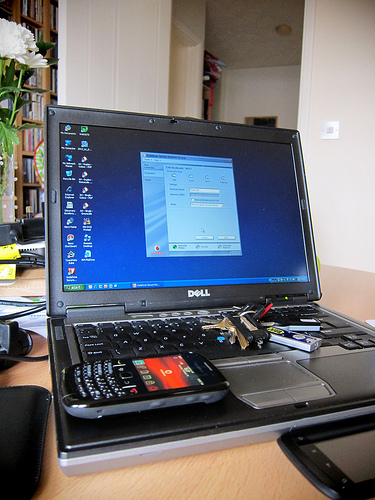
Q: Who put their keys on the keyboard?
A: The owner.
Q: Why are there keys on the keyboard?
A: For typing.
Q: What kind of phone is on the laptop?
A: Blackberry.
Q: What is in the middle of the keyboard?
A: Keys.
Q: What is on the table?
A: A laptop.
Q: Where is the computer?
A: On a table.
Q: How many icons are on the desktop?
A: Nineteen.